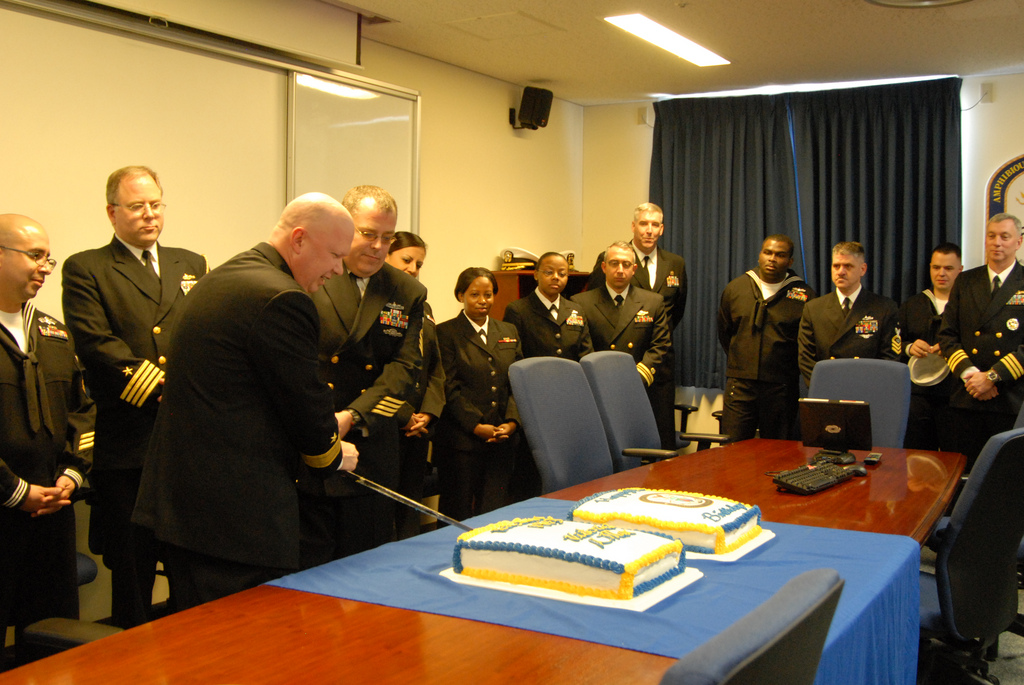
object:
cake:
[452, 516, 687, 601]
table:
[0, 438, 964, 685]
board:
[287, 69, 421, 236]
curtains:
[649, 77, 961, 390]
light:
[603, 11, 727, 69]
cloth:
[263, 496, 922, 684]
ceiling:
[0, 0, 1024, 109]